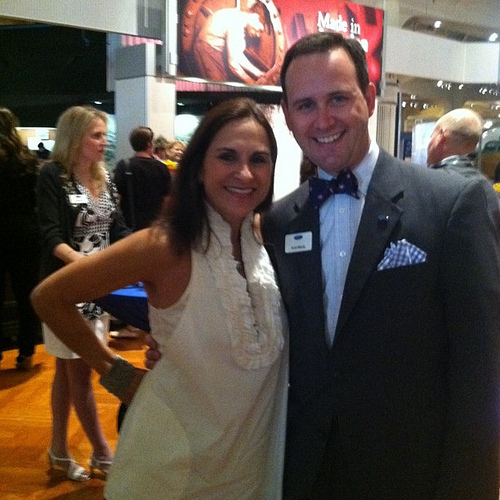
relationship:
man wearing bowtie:
[267, 29, 496, 499] [296, 168, 364, 202]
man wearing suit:
[267, 29, 496, 499] [258, 168, 498, 500]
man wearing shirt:
[267, 29, 496, 499] [309, 133, 389, 347]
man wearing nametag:
[267, 29, 496, 499] [281, 232, 318, 258]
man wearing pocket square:
[267, 29, 496, 499] [371, 236, 434, 275]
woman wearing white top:
[27, 83, 296, 497] [105, 203, 298, 500]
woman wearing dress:
[19, 104, 131, 485] [32, 158, 128, 360]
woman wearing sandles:
[19, 104, 131, 485] [35, 445, 124, 485]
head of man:
[267, 28, 395, 170] [267, 29, 496, 499]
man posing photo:
[267, 29, 496, 499] [3, 3, 499, 498]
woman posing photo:
[27, 83, 296, 497] [3, 3, 499, 498]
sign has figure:
[148, 3, 400, 97] [193, 4, 275, 84]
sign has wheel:
[148, 3, 400, 97] [175, 3, 291, 93]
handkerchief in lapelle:
[371, 236, 434, 275] [377, 252, 436, 279]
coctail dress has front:
[105, 203, 298, 500] [191, 209, 291, 470]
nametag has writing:
[281, 232, 318, 258] [280, 241, 318, 253]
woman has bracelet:
[27, 83, 296, 497] [87, 353, 143, 398]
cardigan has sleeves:
[32, 158, 128, 360] [28, 171, 77, 259]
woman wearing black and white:
[19, 104, 131, 485] [27, 162, 125, 485]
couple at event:
[29, 30, 497, 497] [1, 8, 496, 499]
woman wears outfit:
[19, 104, 131, 485] [27, 162, 125, 485]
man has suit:
[267, 29, 496, 499] [258, 168, 498, 500]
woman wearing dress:
[27, 83, 296, 497] [105, 203, 298, 500]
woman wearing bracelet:
[27, 83, 296, 497] [87, 353, 143, 398]